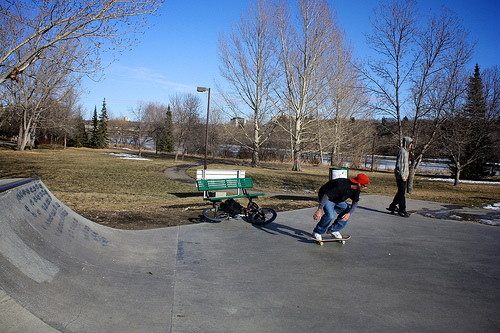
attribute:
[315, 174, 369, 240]
man — walking, riding, crouching down, skating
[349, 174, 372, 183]
hat — red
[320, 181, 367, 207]
shirt — black, grey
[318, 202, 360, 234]
jeans — blue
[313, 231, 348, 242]
shoe — white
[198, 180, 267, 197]
bench — green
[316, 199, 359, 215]
shirt — grey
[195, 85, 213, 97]
light — tall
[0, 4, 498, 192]
tree — tall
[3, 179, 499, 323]
ramp — cement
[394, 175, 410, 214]
jeans — black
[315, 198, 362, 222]
jacket — grey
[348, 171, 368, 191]
cap — red